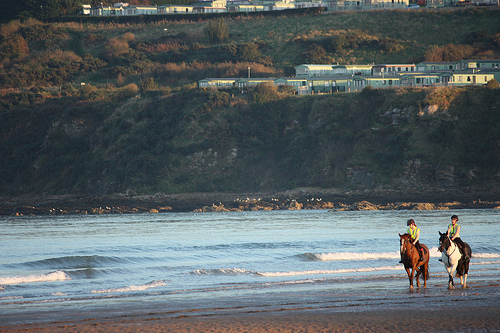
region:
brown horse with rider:
[393, 215, 435, 287]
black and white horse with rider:
[435, 214, 476, 287]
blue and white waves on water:
[27, 223, 231, 290]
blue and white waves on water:
[220, 222, 390, 289]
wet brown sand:
[141, 296, 391, 326]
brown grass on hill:
[31, 87, 203, 184]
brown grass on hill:
[221, 100, 378, 177]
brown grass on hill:
[361, 100, 484, 187]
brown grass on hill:
[41, 27, 283, 62]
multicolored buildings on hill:
[251, 53, 483, 108]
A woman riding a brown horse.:
[368, 206, 434, 294]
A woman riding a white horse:
[428, 207, 476, 290]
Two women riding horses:
[388, 209, 480, 295]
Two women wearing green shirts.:
[393, 206, 463, 238]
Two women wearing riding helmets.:
[404, 215, 460, 225]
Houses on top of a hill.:
[185, 45, 497, 113]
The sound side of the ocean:
[56, 154, 371, 322]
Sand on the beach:
[113, 292, 353, 329]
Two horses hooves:
[404, 278, 483, 298]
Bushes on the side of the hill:
[26, 35, 109, 101]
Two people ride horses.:
[369, 205, 483, 301]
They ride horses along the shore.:
[211, 210, 497, 332]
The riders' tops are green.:
[403, 221, 465, 242]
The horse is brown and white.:
[432, 230, 479, 290]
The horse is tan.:
[387, 232, 434, 297]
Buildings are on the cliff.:
[169, 47, 499, 104]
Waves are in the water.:
[0, 234, 385, 308]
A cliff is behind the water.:
[0, 68, 498, 208]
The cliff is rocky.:
[330, 95, 477, 203]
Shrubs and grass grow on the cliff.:
[0, 17, 388, 97]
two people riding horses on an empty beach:
[393, 211, 478, 303]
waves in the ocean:
[15, 248, 365, 285]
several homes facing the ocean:
[190, 61, 486, 82]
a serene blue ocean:
[38, 225, 324, 248]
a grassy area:
[230, 15, 475, 31]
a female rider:
[403, 217, 418, 239]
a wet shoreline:
[42, 293, 488, 326]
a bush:
[205, 16, 227, 41]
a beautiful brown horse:
[400, 233, 430, 289]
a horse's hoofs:
[404, 279, 431, 291]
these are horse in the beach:
[398, 234, 470, 294]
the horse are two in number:
[391, 233, 474, 280]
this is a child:
[406, 218, 419, 234]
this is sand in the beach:
[278, 308, 328, 325]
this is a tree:
[208, 16, 226, 41]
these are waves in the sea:
[44, 249, 104, 279]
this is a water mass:
[136, 220, 183, 250]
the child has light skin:
[416, 231, 419, 240]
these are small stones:
[102, 192, 147, 207]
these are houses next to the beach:
[301, 63, 448, 83]